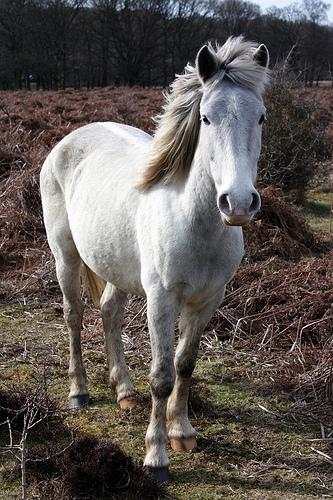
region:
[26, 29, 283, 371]
this is a horse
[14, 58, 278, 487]
the horse is white in color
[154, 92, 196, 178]
the horse is fury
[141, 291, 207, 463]
the legs are strong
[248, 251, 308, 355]
the grass are brown in color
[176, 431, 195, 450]
this is a hoof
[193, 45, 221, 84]
this is the ear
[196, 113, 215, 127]
this is the eye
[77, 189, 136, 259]
the belly is fat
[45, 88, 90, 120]
the grass is in heap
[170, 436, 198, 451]
White horse hoof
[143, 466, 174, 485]
Black horse hoof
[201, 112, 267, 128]
Two black eyes on a horse looking forward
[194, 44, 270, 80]
Two ears on a horse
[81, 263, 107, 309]
White tail of a horse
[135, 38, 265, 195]
White hair on a horse's mane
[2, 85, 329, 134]
Straw in a field behind a horse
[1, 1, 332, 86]
Leafless trees behind a horse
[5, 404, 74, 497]
Stick on the ground in front of a horse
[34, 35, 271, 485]
White horse standing in a field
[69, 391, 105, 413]
the hove is black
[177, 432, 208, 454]
the hove is orange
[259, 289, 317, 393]
the grass is dry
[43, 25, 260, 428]
the horde is white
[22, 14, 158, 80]
trees are in the background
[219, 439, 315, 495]
shadow is on the ground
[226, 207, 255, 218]
red stain is on the nose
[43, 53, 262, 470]
the horse is white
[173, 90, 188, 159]
the mane is white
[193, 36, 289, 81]
the ears are two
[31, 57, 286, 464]
the horse is white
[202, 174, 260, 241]
the nostrils are wide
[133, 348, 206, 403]
the knees are dark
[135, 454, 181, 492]
the right hoof is black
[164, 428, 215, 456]
the left hoof is tan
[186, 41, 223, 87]
the inside of the ear is black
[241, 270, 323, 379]
hay is to the right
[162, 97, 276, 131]
the eyes are black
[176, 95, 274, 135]
the eyes are open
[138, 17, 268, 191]
the mane is blowing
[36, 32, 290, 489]
a white horse is standing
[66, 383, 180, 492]
two black hooves on horse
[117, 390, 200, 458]
two tan hooves on horse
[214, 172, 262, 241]
white nose of horse with two red spots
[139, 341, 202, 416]
dirty front knees on horse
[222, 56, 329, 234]
a large dying shrub behind horse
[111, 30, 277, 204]
a long white mane on horse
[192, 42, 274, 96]
Black inside white ears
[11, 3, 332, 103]
a row of trees in the distance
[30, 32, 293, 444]
one white horse standing alone